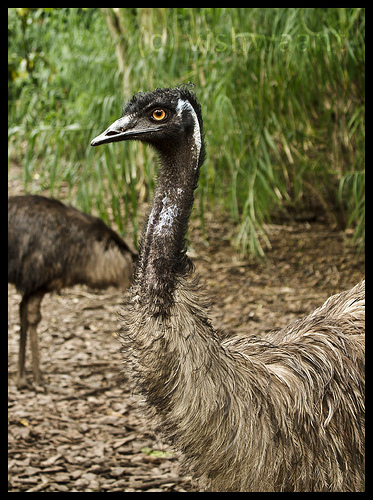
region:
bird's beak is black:
[92, 119, 129, 148]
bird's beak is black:
[77, 116, 147, 150]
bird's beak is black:
[89, 111, 142, 147]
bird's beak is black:
[83, 111, 132, 142]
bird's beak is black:
[85, 108, 139, 146]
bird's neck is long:
[109, 152, 228, 337]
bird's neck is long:
[126, 147, 195, 314]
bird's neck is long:
[111, 151, 190, 334]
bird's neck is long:
[122, 163, 206, 328]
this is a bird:
[94, 96, 365, 493]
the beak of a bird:
[79, 109, 128, 165]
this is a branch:
[81, 157, 147, 229]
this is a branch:
[226, 30, 311, 130]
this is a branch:
[46, 10, 125, 110]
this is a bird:
[10, 191, 134, 392]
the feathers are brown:
[143, 333, 344, 480]